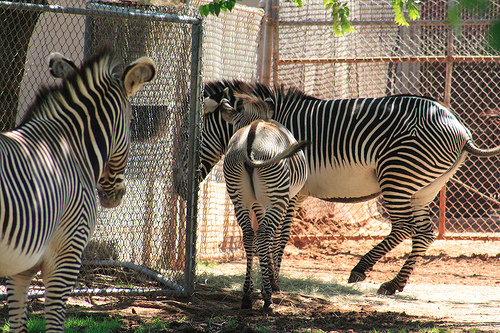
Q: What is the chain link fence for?
A: Contain the animals.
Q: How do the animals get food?
A: They are fed.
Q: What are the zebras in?
A: An enclosure.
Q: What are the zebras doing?
A: Standing.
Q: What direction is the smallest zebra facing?
A: Away from the camera.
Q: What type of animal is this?
A: A zebra.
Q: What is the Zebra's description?
A: Black and white stripes.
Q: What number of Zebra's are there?
A: Three.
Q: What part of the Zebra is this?
A: His rear end.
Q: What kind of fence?
A: Chain link.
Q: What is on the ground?
A: Dirt and grass.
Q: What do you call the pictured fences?
A: Chain link.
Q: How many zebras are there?
A: Three.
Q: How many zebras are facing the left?
A: One.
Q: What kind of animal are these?
A: Zebras.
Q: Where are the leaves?
A: On the trees.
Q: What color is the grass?
A: Green.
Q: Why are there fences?
A: To keep the zebras in.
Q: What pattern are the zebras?
A: Stripes.